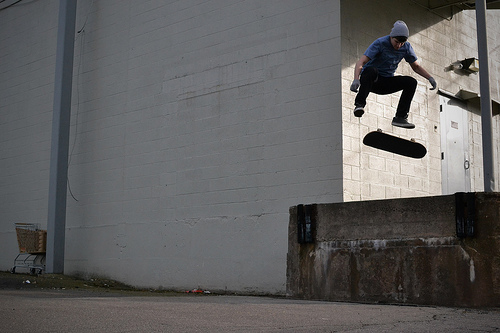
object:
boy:
[349, 20, 436, 129]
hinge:
[440, 105, 444, 113]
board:
[362, 128, 427, 159]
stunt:
[189, 242, 249, 274]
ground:
[384, 193, 445, 242]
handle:
[464, 160, 471, 169]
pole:
[45, 6, 75, 278]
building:
[4, 0, 500, 310]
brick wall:
[179, 53, 340, 197]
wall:
[3, 0, 498, 305]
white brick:
[3, 2, 498, 314]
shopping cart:
[10, 222, 47, 274]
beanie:
[389, 20, 410, 39]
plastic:
[29, 238, 35, 250]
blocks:
[0, 190, 499, 332]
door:
[437, 91, 472, 194]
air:
[0, 0, 499, 332]